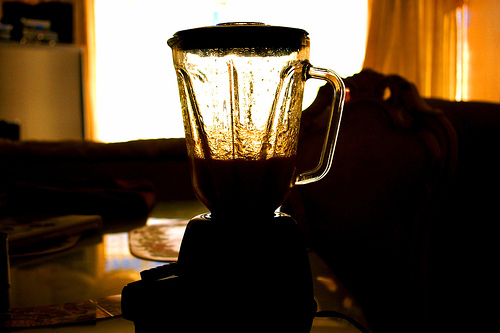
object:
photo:
[9, 10, 484, 314]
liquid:
[189, 154, 296, 213]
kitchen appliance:
[165, 20, 347, 278]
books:
[0, 0, 75, 46]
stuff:
[129, 219, 189, 262]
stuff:
[88, 294, 120, 319]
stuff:
[3, 297, 97, 329]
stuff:
[7, 214, 102, 248]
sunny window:
[93, 2, 370, 144]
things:
[13, 18, 59, 44]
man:
[301, 68, 464, 270]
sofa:
[300, 99, 498, 331]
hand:
[384, 73, 423, 102]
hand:
[319, 78, 350, 101]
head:
[346, 67, 388, 104]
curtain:
[361, 0, 500, 101]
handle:
[294, 65, 346, 186]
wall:
[4, 0, 102, 150]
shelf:
[0, 0, 82, 48]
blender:
[165, 21, 346, 303]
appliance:
[174, 211, 315, 302]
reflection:
[100, 215, 180, 271]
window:
[91, 0, 500, 142]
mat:
[128, 221, 190, 263]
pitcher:
[168, 21, 346, 220]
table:
[6, 212, 245, 331]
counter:
[0, 194, 500, 333]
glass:
[166, 20, 347, 222]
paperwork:
[7, 294, 122, 330]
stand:
[122, 213, 317, 333]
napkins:
[129, 220, 188, 263]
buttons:
[140, 262, 176, 279]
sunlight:
[1, 2, 499, 330]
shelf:
[0, 43, 86, 138]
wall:
[0, 1, 84, 140]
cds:
[0, 0, 75, 46]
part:
[129, 220, 186, 262]